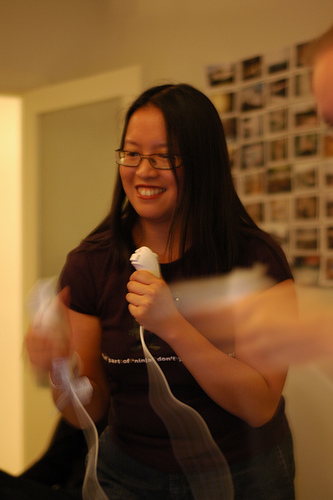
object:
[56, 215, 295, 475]
shirt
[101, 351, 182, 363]
lettering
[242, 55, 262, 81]
picture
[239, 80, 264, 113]
picture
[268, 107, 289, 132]
picture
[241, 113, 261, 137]
picture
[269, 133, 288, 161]
picture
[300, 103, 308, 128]
ground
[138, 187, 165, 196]
teeth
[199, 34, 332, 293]
wall photos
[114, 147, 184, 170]
framed glasses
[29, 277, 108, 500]
wii controller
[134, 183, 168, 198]
smile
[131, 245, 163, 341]
wii game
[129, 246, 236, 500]
wii controller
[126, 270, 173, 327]
hand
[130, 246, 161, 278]
controller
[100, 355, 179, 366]
slogan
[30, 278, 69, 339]
controller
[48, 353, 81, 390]
wrap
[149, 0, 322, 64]
wall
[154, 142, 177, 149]
eyebrow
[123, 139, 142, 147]
eyebrow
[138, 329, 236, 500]
wire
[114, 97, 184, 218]
face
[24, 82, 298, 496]
girl